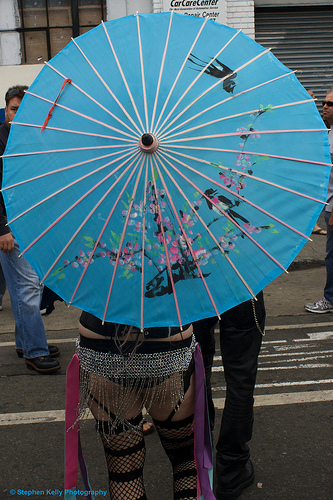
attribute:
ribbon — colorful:
[62, 352, 85, 498]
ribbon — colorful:
[188, 342, 218, 498]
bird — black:
[187, 51, 235, 94]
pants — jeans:
[196, 304, 293, 499]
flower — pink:
[73, 170, 245, 274]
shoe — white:
[302, 295, 331, 312]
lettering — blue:
[16, 497, 107, 499]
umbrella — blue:
[0, 10, 332, 333]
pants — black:
[217, 284, 268, 461]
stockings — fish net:
[97, 422, 148, 499]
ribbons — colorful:
[49, 354, 293, 491]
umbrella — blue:
[32, 64, 271, 285]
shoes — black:
[14, 342, 62, 375]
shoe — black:
[194, 437, 271, 497]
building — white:
[1, 1, 332, 123]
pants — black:
[183, 295, 266, 476]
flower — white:
[89, 155, 229, 270]